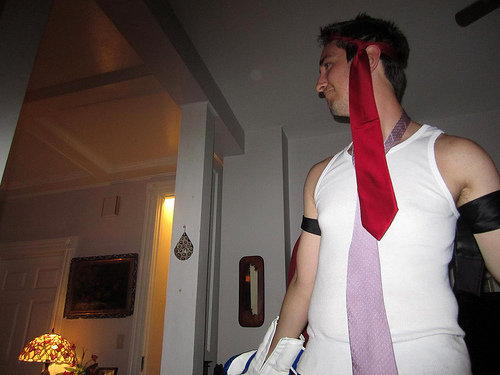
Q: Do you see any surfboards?
A: No, there are no surfboards.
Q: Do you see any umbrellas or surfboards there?
A: No, there are no surfboards or umbrellas.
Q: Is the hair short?
A: Yes, the hair is short.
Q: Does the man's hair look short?
A: Yes, the hair is short.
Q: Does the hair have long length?
A: No, the hair is short.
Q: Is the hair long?
A: No, the hair is short.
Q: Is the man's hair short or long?
A: The hair is short.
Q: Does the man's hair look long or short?
A: The hair is short.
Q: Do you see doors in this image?
A: Yes, there is a door.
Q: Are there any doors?
A: Yes, there is a door.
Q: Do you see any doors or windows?
A: Yes, there is a door.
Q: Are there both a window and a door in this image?
A: No, there is a door but no windows.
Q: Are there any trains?
A: No, there are no trains.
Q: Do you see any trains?
A: No, there are no trains.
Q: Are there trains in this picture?
A: No, there are no trains.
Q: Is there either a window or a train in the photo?
A: No, there are no trains or windows.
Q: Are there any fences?
A: No, there are no fences.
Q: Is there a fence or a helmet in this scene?
A: No, there are no fences or helmets.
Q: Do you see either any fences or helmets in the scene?
A: No, there are no fences or helmets.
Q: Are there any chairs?
A: No, there are no chairs.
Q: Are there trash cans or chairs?
A: No, there are no chairs or trash cans.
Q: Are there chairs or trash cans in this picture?
A: No, there are no chairs or trash cans.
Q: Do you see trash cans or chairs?
A: No, there are no chairs or trash cans.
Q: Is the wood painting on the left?
A: Yes, the painting is on the left of the image.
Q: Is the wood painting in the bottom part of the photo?
A: Yes, the painting is in the bottom of the image.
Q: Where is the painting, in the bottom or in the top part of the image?
A: The painting is in the bottom of the image.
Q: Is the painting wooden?
A: Yes, the painting is wooden.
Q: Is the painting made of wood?
A: Yes, the painting is made of wood.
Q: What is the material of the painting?
A: The painting is made of wood.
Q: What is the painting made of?
A: The painting is made of wood.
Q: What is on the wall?
A: The painting is on the wall.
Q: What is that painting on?
A: The painting is on the wall.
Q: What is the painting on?
A: The painting is on the wall.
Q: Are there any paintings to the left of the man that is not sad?
A: Yes, there is a painting to the left of the man.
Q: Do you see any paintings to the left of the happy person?
A: Yes, there is a painting to the left of the man.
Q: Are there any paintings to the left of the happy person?
A: Yes, there is a painting to the left of the man.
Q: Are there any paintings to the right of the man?
A: No, the painting is to the left of the man.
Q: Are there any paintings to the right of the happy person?
A: No, the painting is to the left of the man.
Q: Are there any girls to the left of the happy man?
A: No, there is a painting to the left of the man.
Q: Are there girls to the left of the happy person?
A: No, there is a painting to the left of the man.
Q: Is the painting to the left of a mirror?
A: No, the painting is to the left of a man.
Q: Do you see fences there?
A: No, there are no fences.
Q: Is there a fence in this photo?
A: No, there are no fences.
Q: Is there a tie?
A: Yes, there is a tie.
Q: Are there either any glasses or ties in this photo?
A: Yes, there is a tie.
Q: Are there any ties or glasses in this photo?
A: Yes, there is a tie.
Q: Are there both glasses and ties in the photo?
A: No, there is a tie but no glasses.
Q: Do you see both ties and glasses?
A: No, there is a tie but no glasses.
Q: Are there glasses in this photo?
A: No, there are no glasses.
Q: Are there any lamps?
A: Yes, there is a lamp.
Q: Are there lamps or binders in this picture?
A: Yes, there is a lamp.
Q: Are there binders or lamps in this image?
A: Yes, there is a lamp.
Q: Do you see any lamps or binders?
A: Yes, there is a lamp.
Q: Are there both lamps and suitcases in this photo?
A: No, there is a lamp but no suitcases.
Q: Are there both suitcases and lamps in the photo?
A: No, there is a lamp but no suitcases.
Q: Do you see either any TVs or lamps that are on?
A: Yes, the lamp is on.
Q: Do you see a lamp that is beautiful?
A: Yes, there is a beautiful lamp.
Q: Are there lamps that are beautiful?
A: Yes, there is a lamp that is beautiful.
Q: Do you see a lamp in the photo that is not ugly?
A: Yes, there is an beautiful lamp.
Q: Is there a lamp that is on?
A: Yes, there is a lamp that is on.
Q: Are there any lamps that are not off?
A: Yes, there is a lamp that is on.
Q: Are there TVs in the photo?
A: No, there are no tvs.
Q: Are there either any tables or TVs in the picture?
A: No, there are no TVs or tables.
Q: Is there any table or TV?
A: No, there are no televisions or tables.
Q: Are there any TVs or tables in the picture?
A: No, there are no TVs or tables.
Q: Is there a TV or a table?
A: No, there are no televisions or tables.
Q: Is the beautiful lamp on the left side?
A: Yes, the lamp is on the left of the image.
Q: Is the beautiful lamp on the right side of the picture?
A: No, the lamp is on the left of the image.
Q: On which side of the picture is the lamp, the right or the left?
A: The lamp is on the left of the image.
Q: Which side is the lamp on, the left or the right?
A: The lamp is on the left of the image.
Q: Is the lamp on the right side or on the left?
A: The lamp is on the left of the image.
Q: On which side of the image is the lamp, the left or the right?
A: The lamp is on the left of the image.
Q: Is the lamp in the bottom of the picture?
A: Yes, the lamp is in the bottom of the image.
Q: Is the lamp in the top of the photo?
A: No, the lamp is in the bottom of the image.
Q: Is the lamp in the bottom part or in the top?
A: The lamp is in the bottom of the image.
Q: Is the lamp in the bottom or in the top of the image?
A: The lamp is in the bottom of the image.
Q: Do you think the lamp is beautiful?
A: Yes, the lamp is beautiful.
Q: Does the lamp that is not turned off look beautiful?
A: Yes, the lamp is beautiful.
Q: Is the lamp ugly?
A: No, the lamp is beautiful.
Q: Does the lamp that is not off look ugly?
A: No, the lamp is beautiful.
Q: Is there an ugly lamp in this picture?
A: No, there is a lamp but it is beautiful.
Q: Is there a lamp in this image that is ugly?
A: No, there is a lamp but it is beautiful.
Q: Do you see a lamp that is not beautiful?
A: No, there is a lamp but it is beautiful.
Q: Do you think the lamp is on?
A: Yes, the lamp is on.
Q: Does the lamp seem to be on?
A: Yes, the lamp is on.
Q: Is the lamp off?
A: No, the lamp is on.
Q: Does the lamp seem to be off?
A: No, the lamp is on.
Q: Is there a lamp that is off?
A: No, there is a lamp but it is on.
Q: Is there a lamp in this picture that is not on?
A: No, there is a lamp but it is on.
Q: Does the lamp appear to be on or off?
A: The lamp is on.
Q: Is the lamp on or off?
A: The lamp is on.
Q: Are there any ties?
A: Yes, there is a tie.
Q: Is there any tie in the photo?
A: Yes, there is a tie.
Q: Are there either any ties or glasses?
A: Yes, there is a tie.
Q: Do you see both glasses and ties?
A: No, there is a tie but no glasses.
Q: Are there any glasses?
A: No, there are no glasses.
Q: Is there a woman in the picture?
A: No, there are no women.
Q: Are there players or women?
A: No, there are no women or players.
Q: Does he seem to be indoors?
A: Yes, the man is indoors.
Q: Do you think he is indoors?
A: Yes, the man is indoors.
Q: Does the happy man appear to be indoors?
A: Yes, the man is indoors.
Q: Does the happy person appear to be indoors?
A: Yes, the man is indoors.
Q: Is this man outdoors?
A: No, the man is indoors.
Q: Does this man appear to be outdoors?
A: No, the man is indoors.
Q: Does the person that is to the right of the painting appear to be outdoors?
A: No, the man is indoors.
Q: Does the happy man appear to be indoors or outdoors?
A: The man is indoors.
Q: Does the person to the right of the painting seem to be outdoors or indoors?
A: The man is indoors.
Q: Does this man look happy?
A: Yes, the man is happy.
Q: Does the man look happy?
A: Yes, the man is happy.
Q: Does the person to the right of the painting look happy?
A: Yes, the man is happy.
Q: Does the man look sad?
A: No, the man is happy.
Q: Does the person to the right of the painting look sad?
A: No, the man is happy.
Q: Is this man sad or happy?
A: The man is happy.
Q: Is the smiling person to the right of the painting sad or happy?
A: The man is happy.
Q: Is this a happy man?
A: Yes, this is a happy man.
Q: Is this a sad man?
A: No, this is a happy man.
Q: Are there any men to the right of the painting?
A: Yes, there is a man to the right of the painting.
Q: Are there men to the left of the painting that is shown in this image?
A: No, the man is to the right of the painting.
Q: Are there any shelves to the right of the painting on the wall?
A: No, there is a man to the right of the painting.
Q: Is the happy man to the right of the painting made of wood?
A: Yes, the man is to the right of the painting.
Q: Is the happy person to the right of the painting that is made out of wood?
A: Yes, the man is to the right of the painting.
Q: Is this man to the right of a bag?
A: No, the man is to the right of the painting.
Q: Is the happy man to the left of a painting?
A: No, the man is to the right of a painting.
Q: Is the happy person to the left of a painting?
A: No, the man is to the right of a painting.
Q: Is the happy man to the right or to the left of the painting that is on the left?
A: The man is to the right of the painting.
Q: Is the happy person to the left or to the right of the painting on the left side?
A: The man is to the right of the painting.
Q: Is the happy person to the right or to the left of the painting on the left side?
A: The man is to the right of the painting.